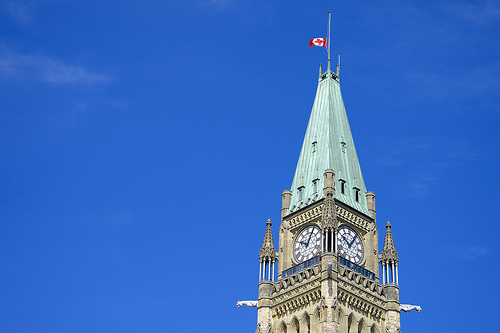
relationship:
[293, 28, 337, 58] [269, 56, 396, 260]
flag on top of tower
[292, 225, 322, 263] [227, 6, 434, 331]
clock on tower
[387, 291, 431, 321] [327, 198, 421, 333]
gargoyle on side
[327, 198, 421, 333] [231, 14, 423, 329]
side of tower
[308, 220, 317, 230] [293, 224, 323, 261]
numeral on face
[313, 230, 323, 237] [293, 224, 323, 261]
numeral on face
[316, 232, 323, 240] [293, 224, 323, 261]
numeral on face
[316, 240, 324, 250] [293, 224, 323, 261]
numeral on face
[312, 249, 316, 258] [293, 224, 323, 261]
numeral on face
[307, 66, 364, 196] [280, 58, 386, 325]
roof on tower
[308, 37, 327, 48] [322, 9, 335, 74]
flag on flagpole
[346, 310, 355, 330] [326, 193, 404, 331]
window on side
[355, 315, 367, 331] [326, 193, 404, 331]
window on side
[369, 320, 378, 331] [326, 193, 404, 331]
window on side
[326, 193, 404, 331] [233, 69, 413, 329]
side of tower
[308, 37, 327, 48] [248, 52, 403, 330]
flag flying over building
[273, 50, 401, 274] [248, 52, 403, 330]
top of building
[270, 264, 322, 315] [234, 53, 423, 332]
trim on tower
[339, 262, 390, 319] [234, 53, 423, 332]
trim on tower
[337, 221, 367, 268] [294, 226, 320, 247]
clock showing 10:05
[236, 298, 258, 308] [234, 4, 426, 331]
decorative piece sticking off building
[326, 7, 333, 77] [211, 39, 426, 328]
slat on top of tower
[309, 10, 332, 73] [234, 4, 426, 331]
flagpole on top of building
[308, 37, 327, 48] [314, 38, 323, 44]
flag with cross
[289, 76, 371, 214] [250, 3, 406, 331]
cap on tower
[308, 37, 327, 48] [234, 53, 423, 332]
flag on tower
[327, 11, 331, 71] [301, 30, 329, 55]
pole with flag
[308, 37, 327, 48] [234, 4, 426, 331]
flag on top of building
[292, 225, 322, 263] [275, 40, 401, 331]
clock on side of building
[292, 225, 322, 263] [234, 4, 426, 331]
clock on side of building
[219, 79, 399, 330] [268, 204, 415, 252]
structure on top of clock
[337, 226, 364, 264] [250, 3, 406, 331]
clock on a tower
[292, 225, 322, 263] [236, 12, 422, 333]
clock on an building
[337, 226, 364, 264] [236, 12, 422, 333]
clock on an building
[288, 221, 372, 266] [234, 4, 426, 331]
clock on an building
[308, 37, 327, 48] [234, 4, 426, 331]
flag on an building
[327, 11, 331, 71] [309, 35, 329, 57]
pole with a flag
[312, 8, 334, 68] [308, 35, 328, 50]
pole with a flag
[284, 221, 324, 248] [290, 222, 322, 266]
hands on clock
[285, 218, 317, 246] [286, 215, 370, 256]
hands on clock